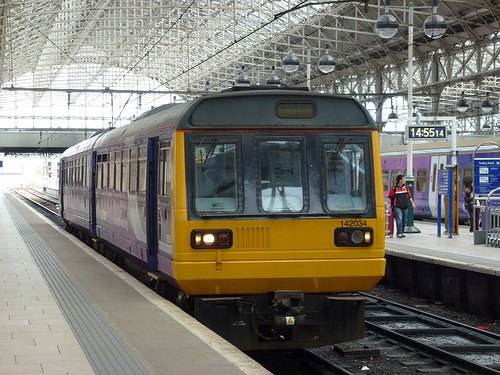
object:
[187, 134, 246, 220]
window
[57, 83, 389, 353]
train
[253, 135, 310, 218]
window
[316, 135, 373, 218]
window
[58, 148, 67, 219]
back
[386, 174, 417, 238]
person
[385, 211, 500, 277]
platform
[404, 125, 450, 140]
clock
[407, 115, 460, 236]
post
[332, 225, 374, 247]
lights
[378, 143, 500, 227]
train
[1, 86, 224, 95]
rails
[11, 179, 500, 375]
tracks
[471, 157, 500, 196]
sign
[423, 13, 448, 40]
lights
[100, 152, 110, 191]
windows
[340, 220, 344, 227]
number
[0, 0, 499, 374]
train station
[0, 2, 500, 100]
ceiling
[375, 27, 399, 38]
glass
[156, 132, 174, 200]
windows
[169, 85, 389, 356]
front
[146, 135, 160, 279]
door